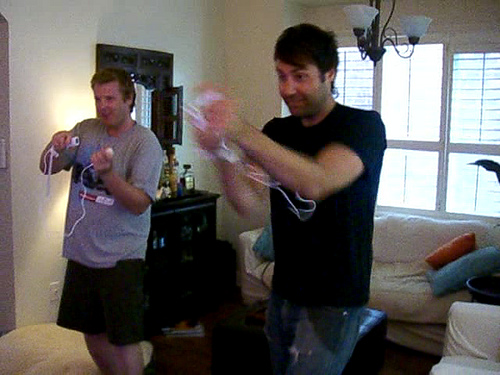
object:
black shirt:
[256, 102, 388, 309]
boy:
[39, 66, 164, 374]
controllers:
[49, 134, 82, 156]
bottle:
[178, 163, 197, 195]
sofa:
[237, 207, 499, 359]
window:
[442, 152, 499, 219]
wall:
[0, 0, 275, 331]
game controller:
[87, 146, 116, 168]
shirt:
[43, 116, 165, 269]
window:
[446, 52, 499, 146]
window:
[375, 44, 441, 145]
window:
[325, 47, 377, 111]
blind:
[329, 45, 374, 111]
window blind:
[447, 52, 499, 145]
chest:
[144, 188, 220, 338]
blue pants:
[257, 293, 367, 373]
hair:
[272, 22, 340, 100]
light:
[341, 0, 380, 63]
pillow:
[422, 230, 479, 269]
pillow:
[422, 246, 498, 298]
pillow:
[248, 224, 278, 263]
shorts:
[56, 252, 158, 347]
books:
[160, 319, 205, 339]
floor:
[143, 302, 445, 373]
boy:
[193, 22, 386, 373]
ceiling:
[293, 0, 496, 7]